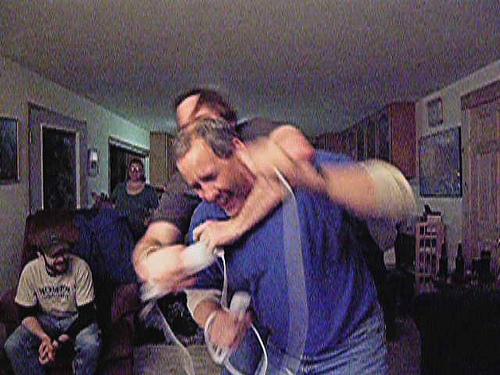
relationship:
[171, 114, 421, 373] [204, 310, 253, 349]
man has hand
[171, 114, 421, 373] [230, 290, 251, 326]
man has remote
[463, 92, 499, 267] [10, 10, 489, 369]
door in a living room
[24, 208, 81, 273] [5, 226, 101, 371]
head of a person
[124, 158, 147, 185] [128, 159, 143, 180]
head of a person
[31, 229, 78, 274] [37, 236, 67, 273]
head of a person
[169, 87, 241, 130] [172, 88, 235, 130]
head of a person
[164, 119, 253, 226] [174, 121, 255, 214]
head of a person